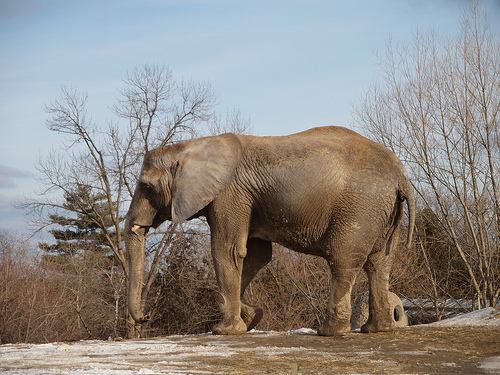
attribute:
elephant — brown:
[112, 143, 430, 341]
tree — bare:
[361, 37, 499, 289]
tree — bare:
[363, 3, 499, 324]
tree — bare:
[381, 30, 495, 373]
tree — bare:
[381, 34, 499, 290]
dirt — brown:
[170, 324, 391, 351]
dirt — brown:
[26, 341, 253, 362]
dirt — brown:
[128, 306, 233, 373]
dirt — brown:
[228, 308, 320, 371]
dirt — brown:
[306, 335, 335, 371]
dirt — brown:
[206, 341, 298, 373]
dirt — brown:
[66, 326, 215, 371]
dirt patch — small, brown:
[447, 333, 485, 351]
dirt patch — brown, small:
[155, 360, 196, 369]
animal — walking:
[123, 123, 417, 336]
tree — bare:
[350, 1, 485, 307]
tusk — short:
[130, 224, 140, 232]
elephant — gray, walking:
[120, 122, 418, 337]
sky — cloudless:
[1, 1, 484, 248]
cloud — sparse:
[2, 165, 33, 187]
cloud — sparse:
[1, 193, 64, 223]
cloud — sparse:
[0, 217, 71, 247]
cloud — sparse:
[6, 35, 131, 74]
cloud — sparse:
[171, 220, 211, 230]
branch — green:
[37, 240, 77, 252]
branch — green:
[45, 210, 85, 224]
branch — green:
[60, 201, 77, 211]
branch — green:
[81, 189, 112, 202]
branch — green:
[82, 241, 113, 254]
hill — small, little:
[458, 308, 484, 325]